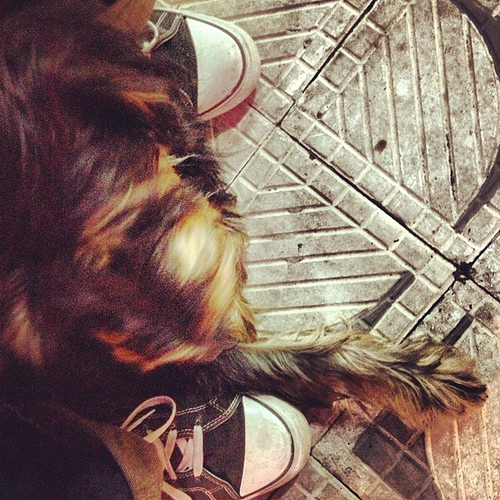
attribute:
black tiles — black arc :
[346, 407, 457, 498]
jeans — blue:
[2, 400, 166, 498]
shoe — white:
[21, 382, 315, 497]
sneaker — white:
[130, 370, 411, 484]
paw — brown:
[252, 327, 487, 428]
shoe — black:
[96, 397, 310, 498]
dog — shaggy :
[4, 25, 499, 477]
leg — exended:
[182, 321, 490, 428]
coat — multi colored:
[2, 8, 498, 360]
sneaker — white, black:
[135, 7, 258, 131]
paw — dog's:
[374, 336, 484, 426]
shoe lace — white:
[113, 396, 206, 471]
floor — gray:
[145, 1, 497, 498]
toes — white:
[203, 0, 353, 151]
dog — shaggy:
[8, 34, 274, 391]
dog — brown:
[0, 12, 480, 462]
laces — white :
[119, 393, 212, 490]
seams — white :
[148, 390, 247, 499]